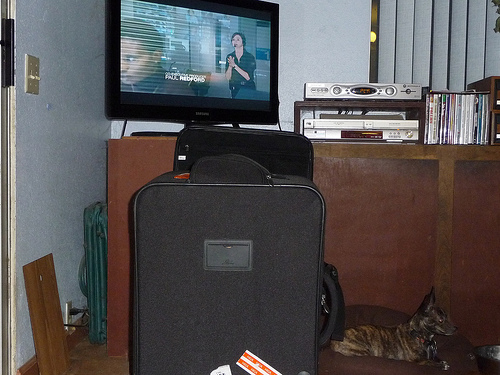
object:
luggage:
[125, 153, 326, 374]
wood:
[23, 253, 75, 375]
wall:
[5, 0, 112, 374]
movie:
[446, 92, 455, 143]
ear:
[412, 295, 430, 318]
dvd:
[431, 95, 437, 145]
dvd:
[438, 91, 448, 140]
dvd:
[449, 92, 457, 140]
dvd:
[463, 96, 470, 147]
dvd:
[469, 96, 479, 145]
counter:
[106, 134, 500, 151]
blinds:
[373, 0, 499, 93]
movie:
[431, 94, 439, 143]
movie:
[455, 93, 461, 146]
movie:
[471, 95, 477, 146]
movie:
[467, 94, 472, 145]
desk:
[105, 137, 499, 356]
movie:
[474, 95, 482, 145]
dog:
[330, 285, 460, 371]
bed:
[316, 303, 481, 374]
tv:
[105, 0, 281, 128]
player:
[300, 120, 421, 131]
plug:
[65, 304, 87, 318]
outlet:
[63, 301, 75, 332]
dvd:
[302, 126, 418, 142]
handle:
[316, 263, 344, 350]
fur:
[366, 339, 409, 349]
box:
[303, 80, 420, 101]